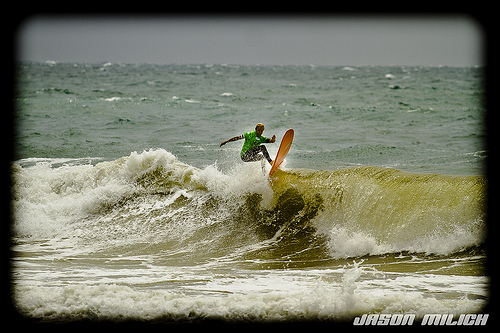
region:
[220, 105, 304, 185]
man surfing in green ocean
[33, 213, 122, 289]
green and white waves on water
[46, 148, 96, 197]
green and white waves on water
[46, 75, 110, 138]
green and white waves on water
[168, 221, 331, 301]
green and white waves on water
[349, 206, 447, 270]
green and white waves on water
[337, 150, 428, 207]
green and white waves on water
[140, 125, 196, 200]
green and white waves on water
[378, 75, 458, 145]
green and white waves on water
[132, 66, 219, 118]
green and white waves on water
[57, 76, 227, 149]
The water is green.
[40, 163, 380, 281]
These are waves.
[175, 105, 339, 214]
The man is surfing.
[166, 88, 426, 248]
He is riding the waves.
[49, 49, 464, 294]
The waters are choppy.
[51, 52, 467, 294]
This is good weather to surf.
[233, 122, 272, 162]
The surfer's shirt is green.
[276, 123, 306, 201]
The surfboard is orange.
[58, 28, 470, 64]
The horizon is gray.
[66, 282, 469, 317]
The seafoam is white.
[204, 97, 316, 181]
The surfer is riding a large wave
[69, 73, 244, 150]
The water is flat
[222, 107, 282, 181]
The surfer has a wetsuit on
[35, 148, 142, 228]
The wave has a white cap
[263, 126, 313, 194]
The surfboard is orange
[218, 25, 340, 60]
The sky is gray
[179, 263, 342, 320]
White foam on the ocean water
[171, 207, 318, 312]
Light reflection on the water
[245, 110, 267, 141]
The man has blonde hair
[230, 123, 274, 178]
the man has on short sleeve top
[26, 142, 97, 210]
white and green waves in ocean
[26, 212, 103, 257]
white and green waves in ocean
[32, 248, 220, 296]
white and green waves in ocean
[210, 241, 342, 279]
white and green waves in ocean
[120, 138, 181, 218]
white and green waves in ocean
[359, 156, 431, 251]
white and green waves in ocean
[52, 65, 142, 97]
white and green waves in ocean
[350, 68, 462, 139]
white and green waves in ocean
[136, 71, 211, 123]
white and green waves in ocean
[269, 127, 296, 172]
orange surfboard in water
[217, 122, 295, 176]
person riding orange surfboard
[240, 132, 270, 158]
person wearing green shirt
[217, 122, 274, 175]
person is wet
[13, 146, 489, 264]
large wave under person surfing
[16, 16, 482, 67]
gray sky above water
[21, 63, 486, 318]
gray water below sky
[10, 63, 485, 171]
clam water is behind person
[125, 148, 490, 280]
wave is orange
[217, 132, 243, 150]
person's arm is out